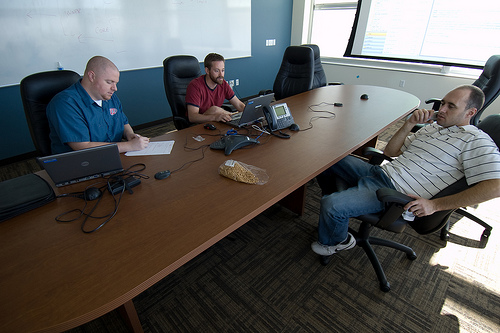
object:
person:
[46, 54, 150, 157]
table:
[0, 84, 421, 333]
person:
[185, 53, 246, 123]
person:
[310, 85, 499, 256]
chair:
[271, 46, 312, 101]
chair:
[162, 55, 200, 131]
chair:
[300, 44, 344, 90]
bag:
[218, 159, 271, 186]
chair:
[20, 70, 82, 157]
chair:
[320, 114, 498, 293]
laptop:
[224, 92, 275, 128]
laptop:
[38, 143, 126, 188]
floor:
[64, 178, 499, 333]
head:
[204, 53, 225, 85]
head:
[84, 56, 120, 101]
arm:
[51, 96, 130, 160]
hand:
[403, 193, 437, 217]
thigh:
[328, 182, 393, 216]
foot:
[311, 232, 357, 256]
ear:
[88, 69, 95, 84]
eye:
[446, 104, 454, 110]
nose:
[111, 82, 117, 91]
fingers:
[403, 198, 418, 211]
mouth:
[435, 113, 448, 120]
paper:
[123, 140, 175, 157]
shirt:
[46, 79, 129, 145]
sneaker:
[311, 231, 357, 256]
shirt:
[183, 73, 235, 114]